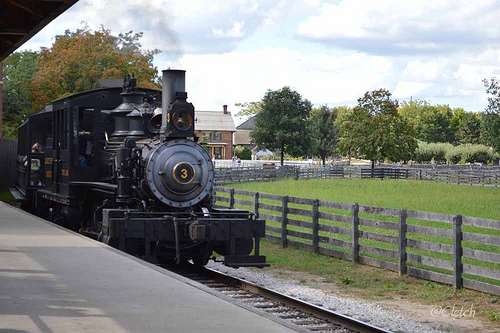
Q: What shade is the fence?
A: Gray.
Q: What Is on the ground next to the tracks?
A: Gravel.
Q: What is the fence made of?
A: Wood.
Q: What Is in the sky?
A: Clouds.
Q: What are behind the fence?
A: Trees.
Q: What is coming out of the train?
A: Smoke.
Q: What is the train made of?
A: Metal.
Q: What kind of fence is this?
A: Wooden.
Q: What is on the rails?
A: Locomotive.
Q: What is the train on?
A: Tracks.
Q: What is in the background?
A: Trees.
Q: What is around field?
A: Fences.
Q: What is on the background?
A: Building.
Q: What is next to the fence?
A: Grass.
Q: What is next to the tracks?
A: Gravel.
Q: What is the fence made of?
A: Wood.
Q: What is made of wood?
A: The fence.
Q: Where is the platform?
A: Near the tracks.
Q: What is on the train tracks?
A: Train.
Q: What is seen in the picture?
A: Train.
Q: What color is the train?
A: Black.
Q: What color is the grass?
A: Green.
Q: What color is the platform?
A: Grey.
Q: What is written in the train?
A: 3.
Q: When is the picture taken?
A: Daytime.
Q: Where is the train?
A: In the track.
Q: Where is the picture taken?
A: Near train.